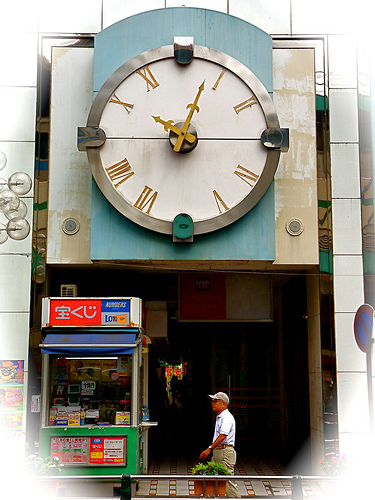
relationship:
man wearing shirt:
[200, 390, 240, 475] [211, 406, 238, 446]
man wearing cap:
[200, 390, 240, 475] [207, 391, 230, 405]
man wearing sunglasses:
[200, 390, 240, 475] [211, 397, 225, 406]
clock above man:
[77, 36, 292, 245] [200, 390, 240, 475]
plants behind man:
[192, 462, 230, 497] [200, 390, 240, 475]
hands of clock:
[148, 77, 212, 154] [77, 36, 292, 245]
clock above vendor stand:
[77, 36, 292, 245] [34, 294, 161, 473]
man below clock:
[200, 390, 240, 475] [77, 36, 292, 245]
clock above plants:
[77, 36, 292, 245] [192, 462, 230, 497]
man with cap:
[200, 390, 240, 475] [207, 391, 230, 405]